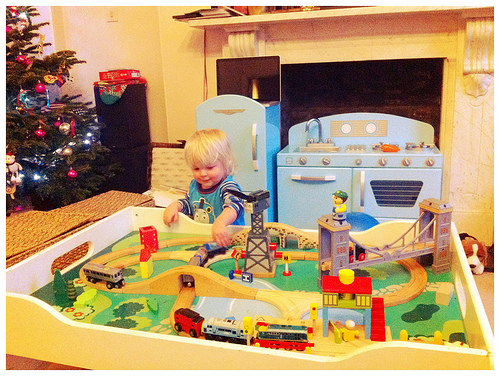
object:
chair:
[195, 94, 269, 223]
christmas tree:
[5, 6, 126, 213]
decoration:
[16, 55, 31, 64]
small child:
[162, 128, 245, 246]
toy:
[172, 306, 317, 354]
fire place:
[280, 58, 447, 152]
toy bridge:
[317, 190, 452, 285]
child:
[162, 128, 245, 246]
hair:
[183, 127, 237, 174]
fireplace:
[184, 5, 491, 245]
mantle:
[187, 4, 492, 29]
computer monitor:
[215, 55, 281, 102]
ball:
[67, 170, 78, 178]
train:
[172, 307, 314, 352]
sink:
[294, 146, 339, 154]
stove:
[353, 167, 443, 219]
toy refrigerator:
[194, 93, 269, 223]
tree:
[6, 7, 124, 213]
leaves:
[76, 149, 109, 177]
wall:
[0, 0, 205, 143]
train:
[181, 241, 226, 288]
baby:
[163, 125, 246, 245]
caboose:
[172, 307, 205, 339]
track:
[78, 222, 428, 359]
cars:
[172, 307, 316, 354]